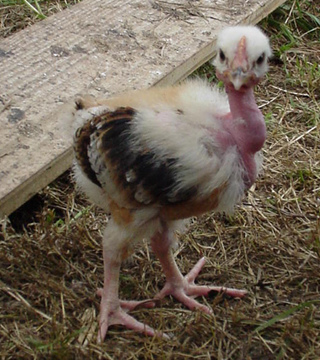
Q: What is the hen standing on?
A: Grass.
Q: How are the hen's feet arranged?
A: Spread apart.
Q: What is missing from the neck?
A: Feathers.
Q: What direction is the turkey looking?
A: Straight ahead.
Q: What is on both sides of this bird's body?
A: Wings.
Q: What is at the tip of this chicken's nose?
A: Beak.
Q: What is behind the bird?
A: Wood plank.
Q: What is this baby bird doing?
A: Standing on the ground.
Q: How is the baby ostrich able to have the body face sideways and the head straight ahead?
A: Ostrich turns neck.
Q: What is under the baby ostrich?
A: Grass.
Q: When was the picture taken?
A: Daytime.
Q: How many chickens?
A: One.